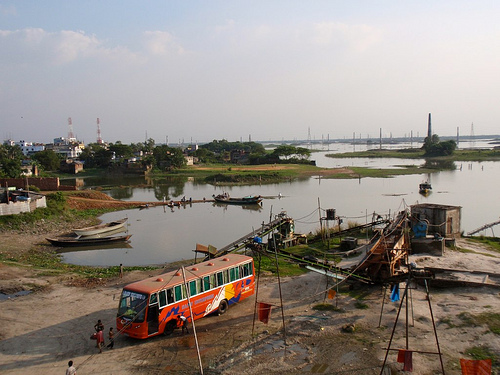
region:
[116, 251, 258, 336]
Orange bus in the mud.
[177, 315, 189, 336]
Guy in a white shirt looking at the front bus tire.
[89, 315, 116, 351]
Three people standing in front of a bus.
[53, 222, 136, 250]
A pair of boats on the left shore.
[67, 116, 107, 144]
Two factory smoke stacks in the distance.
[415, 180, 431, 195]
A boat on the right in the middle of the water.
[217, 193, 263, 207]
One boat tied up to a small dock in the center of the water.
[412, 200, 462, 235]
A shack on the edge of the water.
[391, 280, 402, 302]
A blue flag hanging from wood poles.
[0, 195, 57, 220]
A white brick fence.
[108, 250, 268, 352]
old orange bus parked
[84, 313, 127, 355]
people standing in front of bus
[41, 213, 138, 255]
two boats on shore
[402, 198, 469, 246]
wood shack on waters edge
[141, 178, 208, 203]
reflection in calm water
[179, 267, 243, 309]
windows on old bus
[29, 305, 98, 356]
shadow of bus on ground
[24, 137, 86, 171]
large building on horizon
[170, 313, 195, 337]
man adjusting bus tire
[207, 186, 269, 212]
boat docked at jetty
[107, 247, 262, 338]
orange bus parked by water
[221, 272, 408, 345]
flags sparsely placed on bare wires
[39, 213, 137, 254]
two boats abandoned on shore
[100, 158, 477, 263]
water of a harbor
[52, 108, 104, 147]
tall red and white tower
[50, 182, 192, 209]
brown ramp of dirt leading into water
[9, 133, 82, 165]
white building in background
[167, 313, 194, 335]
man working on bus tire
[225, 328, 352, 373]
wet sand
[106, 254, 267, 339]
red tour bus in the sand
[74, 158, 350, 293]
swamp or lagoon has a boat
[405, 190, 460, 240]
small block building on the shore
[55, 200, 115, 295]
grass growing at the edge of the lagoon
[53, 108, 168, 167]
radio towers in the distance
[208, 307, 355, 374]
mud puddles near the bus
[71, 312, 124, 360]
people waiting for the bus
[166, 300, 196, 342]
man working on bus tire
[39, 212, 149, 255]
two small wood boats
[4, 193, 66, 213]
white fence surrounding property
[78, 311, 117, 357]
woman wearing orange skirt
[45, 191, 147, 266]
two motor less boats in a lake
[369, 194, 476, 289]
storage building on the edge of a lake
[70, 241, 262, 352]
large orange bus parked by a lake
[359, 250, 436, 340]
blue cloth hanging on a metal frame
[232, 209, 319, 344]
orange cloth hanging on a metal frame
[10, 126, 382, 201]
several green trees planted by water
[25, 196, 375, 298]
green grass located by the lake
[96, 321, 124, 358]
small child standing with woman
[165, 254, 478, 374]
large sandy area next to a lake